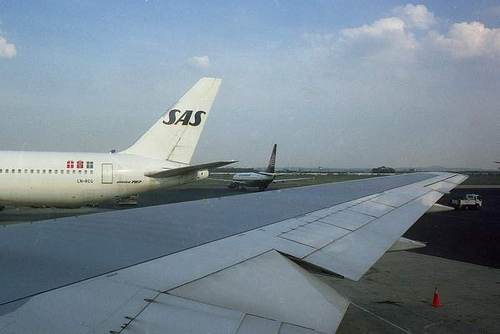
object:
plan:
[207, 144, 277, 191]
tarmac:
[315, 250, 500, 334]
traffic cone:
[433, 287, 440, 306]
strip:
[435, 290, 438, 292]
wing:
[3, 170, 468, 334]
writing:
[163, 109, 207, 126]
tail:
[116, 76, 220, 164]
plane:
[1, 78, 238, 208]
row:
[2, 170, 93, 174]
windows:
[90, 170, 93, 174]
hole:
[276, 251, 345, 279]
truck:
[451, 194, 482, 211]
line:
[349, 300, 409, 333]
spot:
[376, 300, 403, 306]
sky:
[0, 0, 499, 179]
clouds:
[304, 0, 497, 76]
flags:
[66, 160, 74, 168]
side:
[169, 169, 208, 187]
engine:
[166, 169, 210, 187]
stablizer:
[117, 193, 138, 204]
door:
[102, 163, 113, 184]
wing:
[144, 161, 238, 178]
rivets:
[103, 292, 166, 333]